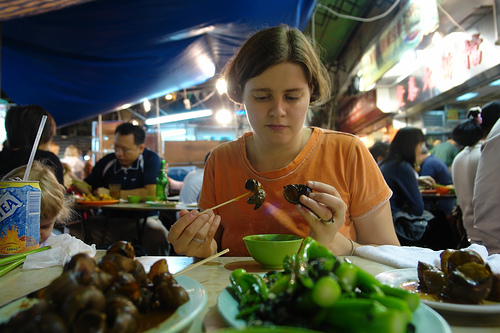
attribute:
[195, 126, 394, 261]
shirt — orange, casual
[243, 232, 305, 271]
bowl — green, small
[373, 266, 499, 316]
plate — white, ceramic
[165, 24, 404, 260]
woman — sitting, eating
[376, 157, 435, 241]
shirt — blue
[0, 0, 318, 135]
tarp — blue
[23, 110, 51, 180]
straw — clear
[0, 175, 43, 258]
can — orange, metal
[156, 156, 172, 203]
bottle — clear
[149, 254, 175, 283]
snail — cooked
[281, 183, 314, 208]
shell — brown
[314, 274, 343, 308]
vegetable — green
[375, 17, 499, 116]
sign — silver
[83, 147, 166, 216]
shirt — dark, blue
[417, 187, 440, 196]
tray — red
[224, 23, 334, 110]
hair — brown, short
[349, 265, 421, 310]
asparagus spear — green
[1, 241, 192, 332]
pile — large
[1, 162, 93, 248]
child — blonde, small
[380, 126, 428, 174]
hair — black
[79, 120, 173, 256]
man — eating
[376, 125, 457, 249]
person — eating